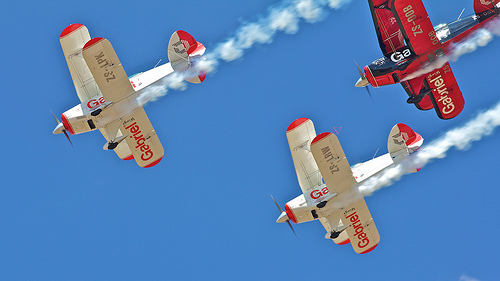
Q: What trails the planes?
A: Smoke.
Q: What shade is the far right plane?
A: Red.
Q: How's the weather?
A: Perfect.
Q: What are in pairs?
A: Wings.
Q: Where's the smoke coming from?
A: Exhaust.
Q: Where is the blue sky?
A: Behind the airplanes.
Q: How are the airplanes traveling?
A: Flying.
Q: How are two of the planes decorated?
A: White with red writing.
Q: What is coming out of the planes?
A: Contrails.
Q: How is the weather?
A: Clear.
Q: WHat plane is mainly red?
A: The trailing plane.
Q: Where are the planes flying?
A: In a clear blue sky.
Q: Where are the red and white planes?
A: In the front.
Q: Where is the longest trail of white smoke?
A: Following the first plane.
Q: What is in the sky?
A: Three stunt airplanes.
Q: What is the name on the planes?
A: Gabriel.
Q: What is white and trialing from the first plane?
A: A plume of exhaust.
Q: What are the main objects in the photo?
A: The three stunt planes.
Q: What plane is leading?
A: The first red and white plane.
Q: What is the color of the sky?
A: Blue.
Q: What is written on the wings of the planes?
A: Gabriel.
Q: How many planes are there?
A: Three.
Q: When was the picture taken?
A: During an airshow.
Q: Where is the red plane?
A: In the back.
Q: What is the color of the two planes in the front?
A: White.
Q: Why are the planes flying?
A: For an airshow.